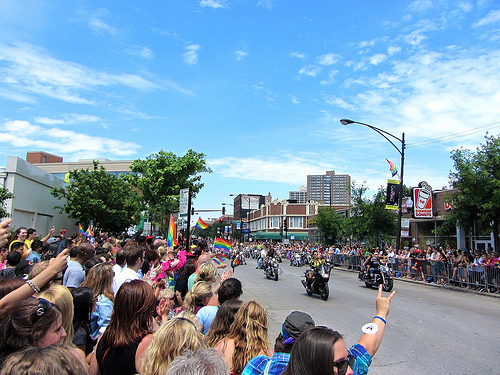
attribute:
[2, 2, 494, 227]
sky — cloudy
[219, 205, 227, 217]
light — traffic light